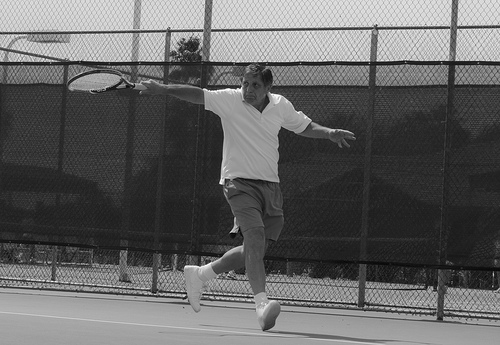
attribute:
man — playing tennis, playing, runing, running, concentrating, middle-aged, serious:
[141, 63, 358, 332]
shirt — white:
[203, 86, 311, 184]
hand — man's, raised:
[138, 78, 165, 97]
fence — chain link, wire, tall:
[0, 0, 498, 321]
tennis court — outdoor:
[0, 286, 499, 343]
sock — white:
[199, 263, 217, 283]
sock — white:
[252, 290, 270, 307]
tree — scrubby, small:
[163, 35, 213, 208]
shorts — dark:
[222, 177, 286, 243]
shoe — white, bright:
[181, 264, 207, 313]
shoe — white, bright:
[257, 299, 283, 330]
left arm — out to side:
[282, 92, 358, 150]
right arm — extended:
[140, 76, 221, 116]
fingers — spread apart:
[336, 127, 358, 152]